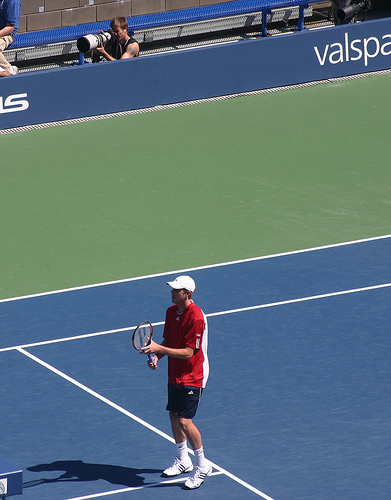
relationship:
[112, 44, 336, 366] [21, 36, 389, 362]
lines in court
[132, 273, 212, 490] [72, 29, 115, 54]
man holding camera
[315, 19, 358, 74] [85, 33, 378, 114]
letters on wall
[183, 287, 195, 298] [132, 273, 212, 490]
ear on man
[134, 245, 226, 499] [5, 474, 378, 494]
tennis player in court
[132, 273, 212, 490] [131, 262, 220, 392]
man wears shirt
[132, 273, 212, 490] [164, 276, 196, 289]
man wears cap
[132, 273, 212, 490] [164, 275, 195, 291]
man wearing cap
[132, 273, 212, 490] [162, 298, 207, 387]
man wearing shirt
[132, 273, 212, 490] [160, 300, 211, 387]
man in shirt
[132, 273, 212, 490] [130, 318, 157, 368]
man holding racket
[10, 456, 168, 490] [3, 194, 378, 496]
shadow on court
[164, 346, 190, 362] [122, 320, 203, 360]
tattoo on arm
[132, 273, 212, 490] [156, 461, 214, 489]
man wearing shoes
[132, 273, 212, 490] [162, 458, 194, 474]
man wearing shoes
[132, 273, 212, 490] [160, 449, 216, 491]
man wearing shoes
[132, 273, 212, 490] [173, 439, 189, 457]
man wearing socks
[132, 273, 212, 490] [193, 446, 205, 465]
man wearing socks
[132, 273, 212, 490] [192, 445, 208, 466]
man wearing sock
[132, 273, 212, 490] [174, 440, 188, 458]
man wearing sock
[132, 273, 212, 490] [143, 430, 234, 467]
man wearing socks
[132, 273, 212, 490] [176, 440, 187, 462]
man wearing sock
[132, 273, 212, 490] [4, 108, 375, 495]
man on court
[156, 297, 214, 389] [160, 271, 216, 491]
shirt on man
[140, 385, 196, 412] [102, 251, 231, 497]
shorts on man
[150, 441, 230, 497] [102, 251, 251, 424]
shoes on man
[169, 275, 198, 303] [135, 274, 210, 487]
head on person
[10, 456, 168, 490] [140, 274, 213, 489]
shadow on person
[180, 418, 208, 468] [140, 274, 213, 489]
leg on person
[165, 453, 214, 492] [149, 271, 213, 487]
feet on person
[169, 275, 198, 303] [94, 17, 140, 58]
head on person